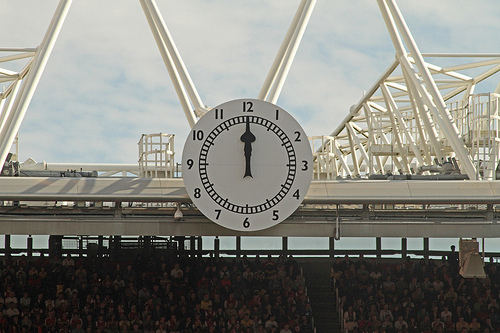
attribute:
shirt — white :
[170, 270, 182, 277]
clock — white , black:
[173, 90, 319, 245]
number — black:
[285, 187, 315, 203]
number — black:
[238, 215, 253, 230]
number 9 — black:
[184, 156, 197, 173]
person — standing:
[447, 242, 457, 274]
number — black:
[212, 206, 224, 221]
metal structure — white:
[1, 0, 499, 200]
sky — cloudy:
[33, 8, 330, 145]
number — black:
[283, 130, 309, 150]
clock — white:
[184, 98, 311, 235]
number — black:
[190, 129, 205, 141]